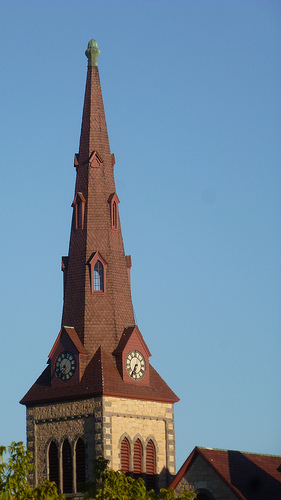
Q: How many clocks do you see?
A: 2.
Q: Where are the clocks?
A: On the building.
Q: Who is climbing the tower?
A: No one.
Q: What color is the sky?
A: Blue.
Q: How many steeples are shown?
A: 1.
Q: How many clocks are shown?
A: 2.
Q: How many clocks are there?
A: Two.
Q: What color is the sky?
A: Blue.